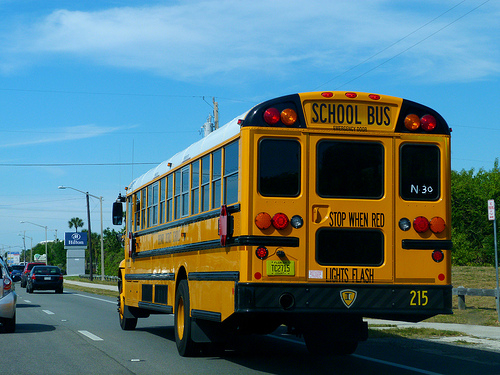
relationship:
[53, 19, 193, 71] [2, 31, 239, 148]
clouds in sky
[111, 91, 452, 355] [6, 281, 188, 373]
automobile driving down road